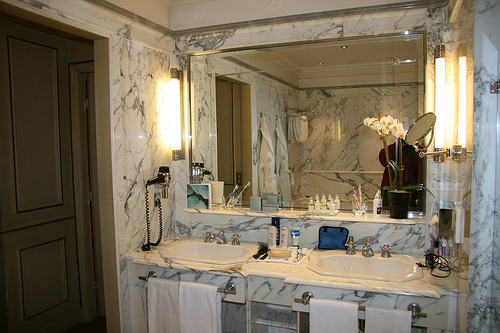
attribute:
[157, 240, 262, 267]
sink — bathroom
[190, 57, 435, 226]
mirror — small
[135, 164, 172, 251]
hair dryer — on wall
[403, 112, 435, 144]
mirror — round, moveable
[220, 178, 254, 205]
toothbrush — blue, white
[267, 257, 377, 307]
marble — wall and sink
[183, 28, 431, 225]
mirror — large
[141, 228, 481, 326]
sink — double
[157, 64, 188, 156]
light — mounted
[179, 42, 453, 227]
mirror — large, silver framed, bathroom